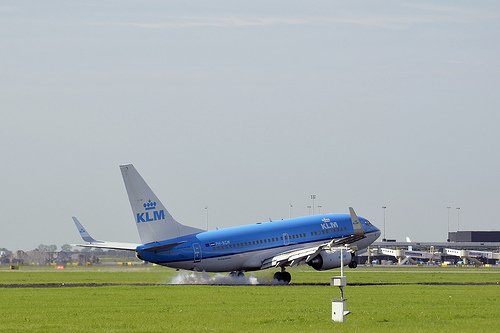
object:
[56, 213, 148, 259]
wing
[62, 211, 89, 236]
tip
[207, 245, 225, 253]
windows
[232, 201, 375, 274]
right wing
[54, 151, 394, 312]
airplane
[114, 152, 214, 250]
airplane tail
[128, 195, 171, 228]
logo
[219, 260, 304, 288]
landing gears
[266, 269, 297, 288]
tires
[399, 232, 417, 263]
lamp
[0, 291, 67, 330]
grass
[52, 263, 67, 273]
red sign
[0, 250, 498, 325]
airport runway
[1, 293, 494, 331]
field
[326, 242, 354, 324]
light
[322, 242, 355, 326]
white box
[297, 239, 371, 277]
jet engine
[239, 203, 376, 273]
wing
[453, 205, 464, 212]
light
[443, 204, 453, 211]
light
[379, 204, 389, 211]
light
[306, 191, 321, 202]
light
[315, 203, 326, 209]
light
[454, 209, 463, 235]
pole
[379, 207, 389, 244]
pole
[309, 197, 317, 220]
pole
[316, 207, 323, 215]
pole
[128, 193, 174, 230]
klm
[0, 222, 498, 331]
airport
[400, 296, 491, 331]
ground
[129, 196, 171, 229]
letters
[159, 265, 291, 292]
smoke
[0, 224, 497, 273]
distance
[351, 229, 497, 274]
terminal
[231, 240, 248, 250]
windows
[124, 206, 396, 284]
body